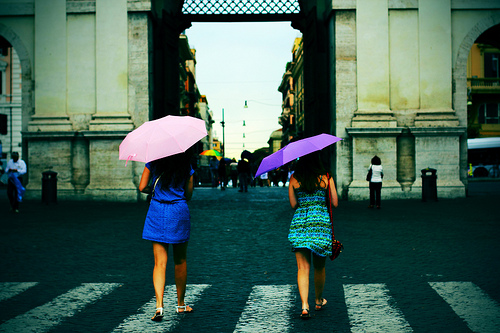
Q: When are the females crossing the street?
A: Now.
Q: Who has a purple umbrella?
A: Girl on right.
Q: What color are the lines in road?
A: White.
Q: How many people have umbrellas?
A: Three.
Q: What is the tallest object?
A: Buildings.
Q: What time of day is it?
A: Daytime.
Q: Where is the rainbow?
A: On umbrella.